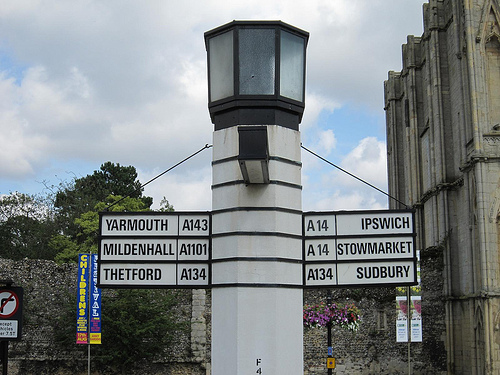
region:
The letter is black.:
[102, 216, 114, 233]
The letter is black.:
[101, 240, 115, 257]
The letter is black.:
[98, 264, 112, 282]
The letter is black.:
[159, 216, 172, 233]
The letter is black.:
[166, 239, 177, 256]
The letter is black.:
[153, 265, 168, 284]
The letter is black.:
[305, 216, 315, 235]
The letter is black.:
[334, 238, 346, 259]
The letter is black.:
[355, 260, 365, 282]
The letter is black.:
[401, 261, 413, 278]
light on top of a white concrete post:
[201, 18, 313, 123]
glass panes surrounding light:
[238, 27, 276, 93]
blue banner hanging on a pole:
[91, 255, 101, 342]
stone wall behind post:
[1, 255, 445, 373]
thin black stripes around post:
[211, 280, 307, 289]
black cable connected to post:
[300, 143, 412, 208]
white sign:
[300, 210, 412, 236]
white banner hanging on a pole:
[410, 250, 422, 342]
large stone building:
[382, 0, 498, 373]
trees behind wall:
[0, 161, 161, 258]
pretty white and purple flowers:
[305, 295, 365, 335]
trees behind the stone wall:
[55, 160, 175, 350]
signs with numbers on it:
[95, 200, 435, 290]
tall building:
[385, 1, 495, 368]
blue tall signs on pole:
[70, 247, 112, 352]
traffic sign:
[0, 275, 33, 356]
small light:
[215, 127, 302, 200]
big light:
[193, 10, 313, 126]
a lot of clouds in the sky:
[5, 12, 185, 145]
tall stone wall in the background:
[11, 263, 243, 365]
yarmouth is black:
[105, 215, 172, 237]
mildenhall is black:
[102, 240, 178, 258]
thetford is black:
[106, 265, 168, 285]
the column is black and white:
[214, 131, 308, 373]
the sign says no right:
[3, 287, 27, 340]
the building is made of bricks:
[382, 71, 498, 269]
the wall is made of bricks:
[322, 302, 379, 355]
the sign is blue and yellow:
[78, 253, 106, 347]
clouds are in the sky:
[83, 90, 160, 125]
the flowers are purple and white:
[309, 306, 362, 331]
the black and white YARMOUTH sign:
[94, 215, 177, 233]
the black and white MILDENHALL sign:
[100, 238, 175, 257]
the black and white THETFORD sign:
[99, 265, 177, 285]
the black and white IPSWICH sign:
[336, 215, 408, 235]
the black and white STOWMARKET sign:
[336, 238, 414, 256]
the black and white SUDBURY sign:
[337, 264, 417, 280]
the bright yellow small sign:
[318, 355, 334, 369]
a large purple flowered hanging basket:
[304, 305, 362, 326]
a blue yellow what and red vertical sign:
[74, 250, 88, 342]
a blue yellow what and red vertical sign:
[90, 253, 105, 345]